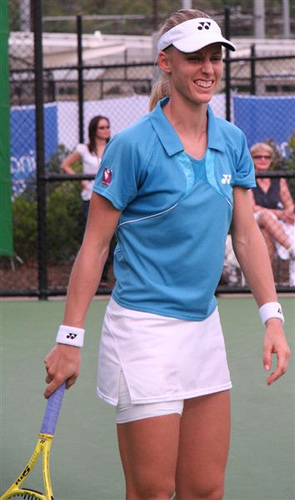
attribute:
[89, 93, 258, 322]
shirt — blue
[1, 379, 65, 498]
tennis racket — yellow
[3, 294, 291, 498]
tennis court — green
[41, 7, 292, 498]
woman — laughing, smiling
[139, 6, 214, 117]
hair — pulled back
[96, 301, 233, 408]
skirt — white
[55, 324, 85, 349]
wrist guard — white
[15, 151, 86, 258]
bush — green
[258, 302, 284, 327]
wrist guard — white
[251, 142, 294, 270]
woman — watching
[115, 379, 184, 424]
shorts — white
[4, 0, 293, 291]
fence — chain link, black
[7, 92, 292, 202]
banner — blue, white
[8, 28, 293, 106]
building — white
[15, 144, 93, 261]
trees — green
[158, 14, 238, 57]
cap — white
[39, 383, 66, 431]
grip — purple